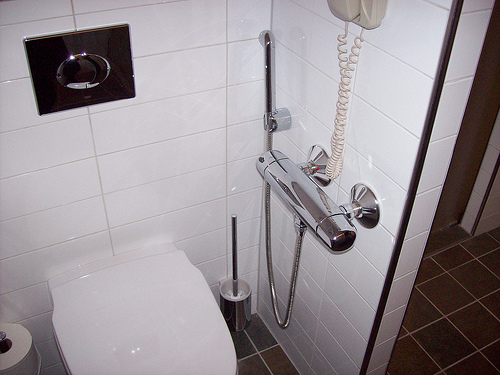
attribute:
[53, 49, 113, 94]
button — round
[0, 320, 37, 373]
tissue — white, round, small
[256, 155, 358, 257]
handlebar — wide, silver, long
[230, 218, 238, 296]
toilet brush — thin, tall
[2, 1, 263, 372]
wall — white, tall, narrow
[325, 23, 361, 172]
cord — hanging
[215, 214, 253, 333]
scrub — thin, silver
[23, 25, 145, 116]
silver — Square,  medium, dark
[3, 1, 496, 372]
tiled wall — white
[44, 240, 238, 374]
toilet — white, closed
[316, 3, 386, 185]
phone — cream-colored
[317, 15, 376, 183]
cord — spiral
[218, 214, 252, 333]
brush — scrub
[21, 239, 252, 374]
toilet — white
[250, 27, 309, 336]
pipe — silver, thin, tall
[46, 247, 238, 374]
tank — oval, white, medium, low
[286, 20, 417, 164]
telephone — tan, curled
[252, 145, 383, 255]
dryer — mounted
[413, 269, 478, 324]
tile — brown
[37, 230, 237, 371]
bowl — low, white, oval, flat